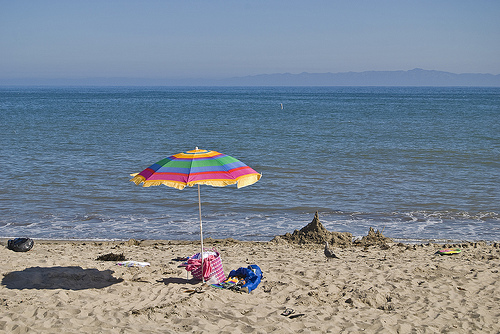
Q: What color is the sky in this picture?
A: Blue.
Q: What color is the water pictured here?
A: Blue.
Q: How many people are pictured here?
A: Zero.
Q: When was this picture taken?
A: Daytime.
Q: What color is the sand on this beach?
A: Tan.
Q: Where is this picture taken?
A: The beach.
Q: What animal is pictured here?
A: Bird.